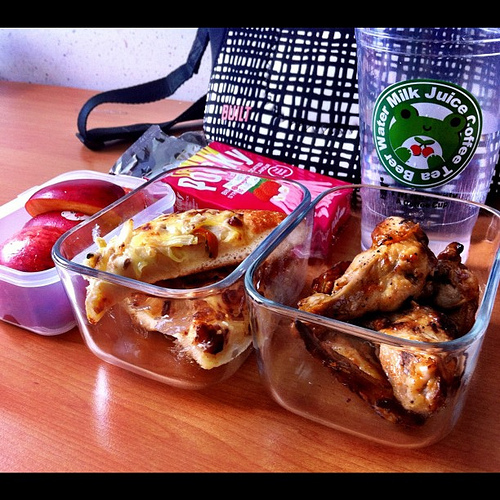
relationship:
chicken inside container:
[82, 207, 297, 372] [49, 166, 312, 393]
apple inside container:
[0, 177, 151, 321] [0, 167, 179, 338]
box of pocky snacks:
[148, 143, 353, 263] [172, 141, 280, 194]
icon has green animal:
[372, 83, 485, 183] [387, 97, 467, 172]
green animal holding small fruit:
[387, 97, 467, 172] [422, 135, 433, 159]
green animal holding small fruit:
[387, 97, 467, 172] [408, 129, 419, 161]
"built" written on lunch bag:
[213, 104, 255, 120] [75, 30, 475, 201]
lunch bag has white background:
[75, 30, 475, 201] [291, 66, 297, 72]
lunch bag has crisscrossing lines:
[75, 30, 475, 201] [265, 54, 314, 113]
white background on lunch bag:
[291, 66, 297, 72] [75, 30, 475, 201]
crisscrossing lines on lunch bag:
[265, 54, 314, 113] [75, 30, 475, 201]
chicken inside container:
[290, 216, 480, 430] [244, 185, 483, 446]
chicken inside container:
[82, 207, 297, 372] [49, 170, 312, 393]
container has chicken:
[244, 185, 483, 446] [290, 216, 480, 430]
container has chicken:
[49, 170, 312, 393] [82, 207, 297, 372]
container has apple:
[0, 167, 181, 337] [0, 177, 151, 321]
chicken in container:
[290, 216, 480, 430] [244, 185, 483, 446]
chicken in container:
[82, 207, 297, 372] [49, 170, 312, 393]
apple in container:
[0, 177, 151, 321] [0, 167, 181, 337]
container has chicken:
[244, 186, 499, 445] [290, 216, 480, 430]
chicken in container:
[290, 216, 480, 430] [244, 186, 499, 445]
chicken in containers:
[82, 207, 297, 372] [84, 172, 418, 402]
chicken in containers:
[290, 216, 480, 430] [78, 153, 453, 392]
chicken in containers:
[290, 216, 480, 430] [116, 169, 468, 419]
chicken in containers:
[113, 190, 245, 320] [140, 148, 486, 425]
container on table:
[244, 186, 499, 445] [170, 393, 448, 490]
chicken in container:
[286, 227, 445, 387] [244, 185, 483, 446]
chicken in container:
[82, 207, 297, 372] [75, 171, 295, 371]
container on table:
[49, 166, 312, 393] [4, 350, 211, 473]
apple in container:
[0, 177, 151, 321] [13, 155, 170, 341]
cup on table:
[328, 43, 474, 239] [24, 370, 311, 494]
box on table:
[148, 143, 353, 263] [15, 352, 291, 472]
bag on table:
[188, 36, 407, 169] [4, 355, 274, 470]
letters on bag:
[205, 87, 291, 131] [214, 47, 404, 232]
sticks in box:
[130, 136, 295, 205] [97, 137, 401, 294]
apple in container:
[0, 177, 151, 321] [23, 156, 189, 355]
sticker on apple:
[51, 188, 97, 223] [5, 180, 115, 264]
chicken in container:
[82, 207, 297, 372] [55, 189, 348, 455]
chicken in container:
[290, 216, 480, 430] [263, 185, 493, 452]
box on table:
[148, 126, 354, 226] [2, 373, 256, 443]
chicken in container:
[82, 207, 297, 372] [46, 158, 307, 382]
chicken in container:
[290, 216, 480, 430] [246, 175, 496, 455]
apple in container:
[1, 173, 151, 321] [0, 167, 181, 337]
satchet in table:
[116, 123, 352, 263] [2, 82, 497, 480]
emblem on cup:
[370, 80, 479, 196] [356, 23, 496, 280]